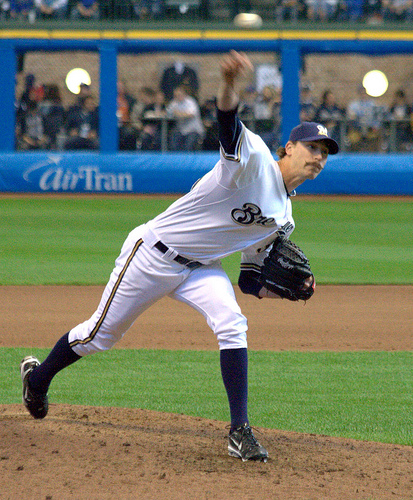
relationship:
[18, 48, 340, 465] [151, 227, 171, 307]
baseball player wearing a belt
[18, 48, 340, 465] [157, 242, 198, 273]
baseball player wearing a belt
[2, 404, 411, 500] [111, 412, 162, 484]
dirt on ground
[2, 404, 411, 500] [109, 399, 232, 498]
dirt on ground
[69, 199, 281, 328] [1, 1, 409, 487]
photo taken at a baseball game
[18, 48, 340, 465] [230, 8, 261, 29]
baseball player pitching baseball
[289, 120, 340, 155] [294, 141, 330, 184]
baseball cap on head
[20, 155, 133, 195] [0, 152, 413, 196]
ad on wall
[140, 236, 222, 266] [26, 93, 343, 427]
belt on uniform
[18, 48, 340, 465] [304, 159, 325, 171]
baseball player has a mustache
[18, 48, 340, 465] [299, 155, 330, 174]
baseball player has a moustache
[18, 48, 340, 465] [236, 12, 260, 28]
baseball player pitching ball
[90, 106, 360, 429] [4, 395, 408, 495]
baseball player on mound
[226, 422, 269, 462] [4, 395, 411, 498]
foot in dirt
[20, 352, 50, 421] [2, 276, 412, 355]
foot in dirt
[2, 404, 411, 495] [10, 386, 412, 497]
dirt covers mound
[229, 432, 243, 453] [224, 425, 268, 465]
nike swoosh on shoe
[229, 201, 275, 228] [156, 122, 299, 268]
logo on front of shirt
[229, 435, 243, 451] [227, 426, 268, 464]
nike on shoe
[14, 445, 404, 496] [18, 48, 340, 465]
mound below baseball player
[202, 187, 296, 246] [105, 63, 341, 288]
logo on shirt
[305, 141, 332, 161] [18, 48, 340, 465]
eyes of baseball player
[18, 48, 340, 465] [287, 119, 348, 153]
baseball player wearing a hat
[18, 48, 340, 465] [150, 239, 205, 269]
baseball player wearing a belt